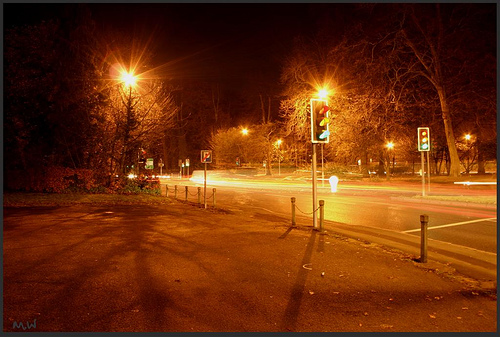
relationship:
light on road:
[323, 173, 340, 193] [135, 168, 498, 255]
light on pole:
[300, 76, 344, 158] [308, 141, 325, 236]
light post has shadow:
[302, 89, 343, 242] [279, 226, 330, 334]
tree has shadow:
[248, 19, 478, 193] [6, 198, 261, 330]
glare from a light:
[332, 196, 378, 230] [85, 50, 194, 113]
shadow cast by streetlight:
[6, 198, 261, 330] [114, 66, 149, 94]